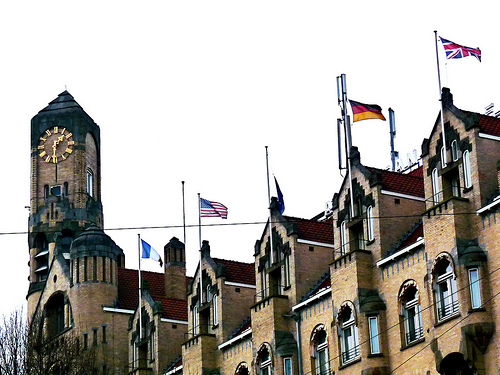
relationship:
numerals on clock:
[56, 136, 96, 156] [35, 124, 77, 167]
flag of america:
[194, 190, 233, 245] [196, 197, 230, 223]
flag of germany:
[343, 97, 384, 149] [350, 99, 386, 125]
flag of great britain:
[432, 30, 488, 84] [437, 34, 483, 61]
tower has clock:
[24, 86, 111, 238] [35, 124, 77, 167]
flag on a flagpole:
[194, 190, 233, 245] [197, 192, 202, 256]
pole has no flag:
[262, 141, 280, 263] [262, 144, 291, 173]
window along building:
[425, 250, 464, 323] [411, 70, 500, 371]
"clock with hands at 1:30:
[35, 124, 77, 167] [50, 128, 67, 165]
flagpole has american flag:
[196, 192, 206, 256] [196, 197, 230, 223]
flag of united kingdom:
[432, 30, 488, 84] [437, 34, 483, 61]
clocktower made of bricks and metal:
[15, 82, 126, 272] [24, 86, 111, 238]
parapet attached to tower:
[21, 227, 69, 280] [24, 86, 111, 238]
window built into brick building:
[425, 250, 464, 323] [411, 70, 500, 371]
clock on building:
[35, 124, 77, 167] [12, 80, 187, 374]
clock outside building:
[35, 124, 77, 167] [12, 80, 187, 374]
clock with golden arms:
[35, 124, 77, 167] [50, 128, 67, 165]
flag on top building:
[194, 190, 233, 245] [177, 235, 260, 374]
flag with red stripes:
[194, 190, 233, 245] [196, 197, 230, 223]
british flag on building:
[432, 30, 488, 84] [411, 70, 500, 371]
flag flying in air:
[194, 190, 233, 245] [6, 4, 482, 251]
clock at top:
[35, 124, 77, 167] [24, 86, 111, 238]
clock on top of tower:
[35, 124, 77, 167] [24, 86, 111, 238]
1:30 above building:
[50, 128, 68, 164] [12, 80, 187, 374]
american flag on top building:
[194, 190, 233, 245] [177, 235, 260, 374]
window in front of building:
[336, 300, 362, 366] [325, 146, 399, 374]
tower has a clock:
[24, 86, 111, 238] [35, 124, 77, 167]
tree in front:
[3, 304, 99, 374] [2, 280, 135, 371]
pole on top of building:
[262, 141, 280, 263] [249, 194, 312, 375]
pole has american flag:
[137, 232, 145, 307] [138, 239, 164, 269]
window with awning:
[39, 270, 50, 282] [33, 263, 53, 275]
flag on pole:
[343, 97, 384, 149] [137, 232, 145, 307]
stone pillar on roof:
[19, 83, 108, 158] [26, 86, 97, 142]